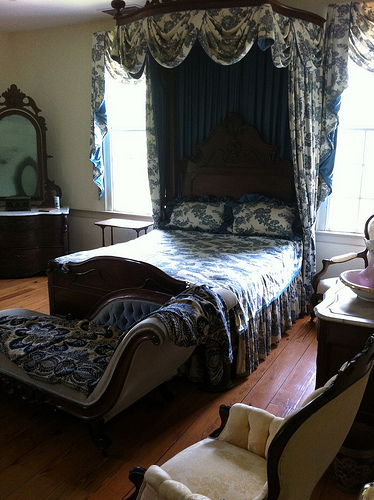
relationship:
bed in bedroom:
[44, 108, 310, 389] [0, 10, 367, 492]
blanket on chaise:
[149, 298, 236, 364] [1, 293, 202, 433]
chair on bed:
[0, 285, 237, 456] [44, 108, 310, 389]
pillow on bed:
[168, 193, 226, 231] [47, 226, 311, 384]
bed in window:
[44, 108, 310, 389] [320, 33, 374, 238]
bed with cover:
[44, 108, 310, 389] [54, 224, 308, 378]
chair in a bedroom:
[128, 333, 373, 498] [0, 10, 367, 492]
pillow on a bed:
[168, 198, 226, 232] [47, 223, 316, 316]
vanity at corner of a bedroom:
[0, 78, 70, 281] [0, 10, 371, 498]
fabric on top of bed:
[164, 237, 273, 262] [48, 196, 332, 369]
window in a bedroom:
[83, 58, 371, 235] [0, 10, 367, 492]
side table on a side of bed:
[93, 215, 155, 245] [46, 208, 294, 304]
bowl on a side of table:
[342, 272, 372, 306] [315, 286, 349, 360]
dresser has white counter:
[0, 206, 69, 278] [0, 207, 69, 213]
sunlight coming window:
[317, 74, 361, 231] [323, 51, 372, 238]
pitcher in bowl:
[349, 217, 362, 282] [329, 236, 372, 312]